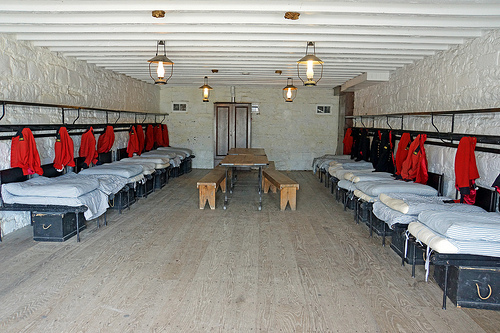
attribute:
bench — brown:
[192, 162, 231, 214]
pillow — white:
[409, 211, 499, 253]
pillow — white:
[6, 181, 101, 215]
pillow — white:
[350, 181, 434, 221]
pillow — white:
[85, 166, 137, 210]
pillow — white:
[324, 164, 370, 189]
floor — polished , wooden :
[0, 170, 498, 331]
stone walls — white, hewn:
[158, 85, 339, 168]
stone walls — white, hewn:
[351, 36, 499, 203]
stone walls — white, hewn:
[1, 39, 160, 235]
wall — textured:
[0, 34, 181, 126]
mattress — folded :
[0, 180, 107, 210]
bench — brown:
[237, 174, 304, 211]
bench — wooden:
[194, 166, 226, 214]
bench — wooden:
[218, 153, 234, 187]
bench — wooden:
[259, 153, 276, 185]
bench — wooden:
[258, 166, 299, 212]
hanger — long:
[26, 103, 176, 128]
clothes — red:
[14, 119, 174, 153]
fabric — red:
[48, 120, 77, 173]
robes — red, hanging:
[7, 120, 499, 182]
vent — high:
[314, 103, 334, 115]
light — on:
[295, 62, 325, 87]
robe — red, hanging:
[6, 136, 38, 175]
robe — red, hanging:
[452, 135, 478, 185]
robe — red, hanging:
[83, 128, 95, 158]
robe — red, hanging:
[410, 134, 429, 175]